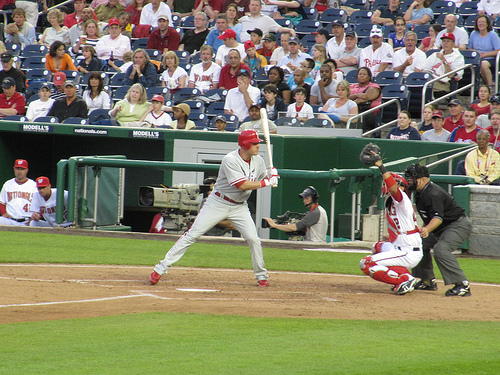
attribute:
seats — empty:
[288, 7, 373, 42]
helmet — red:
[227, 122, 267, 160]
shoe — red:
[146, 265, 167, 288]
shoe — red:
[251, 272, 272, 289]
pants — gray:
[413, 213, 483, 294]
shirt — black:
[404, 180, 463, 234]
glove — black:
[354, 139, 393, 175]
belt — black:
[391, 240, 431, 259]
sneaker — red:
[141, 264, 168, 294]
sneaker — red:
[249, 270, 279, 294]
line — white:
[104, 289, 140, 305]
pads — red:
[368, 268, 395, 287]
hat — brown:
[170, 95, 197, 116]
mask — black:
[401, 164, 423, 201]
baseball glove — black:
[350, 136, 388, 185]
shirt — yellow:
[466, 150, 493, 185]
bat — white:
[259, 109, 275, 179]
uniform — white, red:
[152, 150, 268, 279]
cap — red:
[14, 157, 25, 169]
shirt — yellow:
[462, 148, 499, 180]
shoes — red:
[148, 268, 269, 282]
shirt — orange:
[44, 54, 74, 68]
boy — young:
[212, 114, 232, 131]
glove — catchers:
[359, 140, 381, 168]